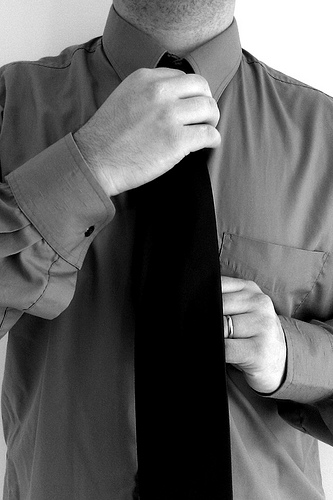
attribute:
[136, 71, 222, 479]
tie — black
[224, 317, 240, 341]
ring — gold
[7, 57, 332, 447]
shirt — long, brown, grey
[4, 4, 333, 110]
wall — white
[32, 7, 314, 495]
man — white